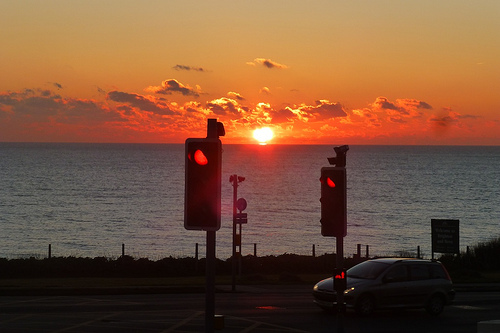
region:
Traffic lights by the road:
[172, 114, 369, 261]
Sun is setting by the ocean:
[215, 83, 355, 183]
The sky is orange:
[132, 10, 347, 140]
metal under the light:
[182, 223, 240, 327]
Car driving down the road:
[314, 235, 478, 312]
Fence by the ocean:
[20, 210, 258, 266]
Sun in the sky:
[233, 114, 296, 161]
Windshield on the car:
[335, 249, 385, 286]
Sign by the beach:
[423, 206, 463, 256]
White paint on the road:
[125, 289, 192, 323]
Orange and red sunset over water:
[1, 3, 494, 250]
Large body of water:
[1, 142, 498, 258]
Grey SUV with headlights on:
[311, 253, 458, 318]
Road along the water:
[0, 235, 499, 328]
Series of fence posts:
[0, 241, 477, 261]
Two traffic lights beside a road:
[183, 117, 350, 329]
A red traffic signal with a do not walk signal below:
[318, 116, 349, 331]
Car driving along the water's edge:
[309, 226, 457, 330]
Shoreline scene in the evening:
[2, 1, 498, 330]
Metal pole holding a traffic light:
[181, 113, 222, 330]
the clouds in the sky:
[0, 52, 499, 147]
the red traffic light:
[192, 148, 208, 163]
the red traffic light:
[324, 175, 336, 187]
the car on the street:
[313, 256, 453, 314]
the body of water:
[3, 141, 498, 256]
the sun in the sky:
[250, 125, 274, 143]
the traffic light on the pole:
[182, 115, 220, 331]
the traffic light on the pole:
[320, 143, 348, 331]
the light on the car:
[343, 286, 354, 295]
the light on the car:
[312, 282, 318, 289]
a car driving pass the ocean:
[318, 250, 490, 308]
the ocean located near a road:
[56, 120, 442, 254]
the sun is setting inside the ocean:
[233, 86, 315, 184]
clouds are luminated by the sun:
[166, 79, 358, 141]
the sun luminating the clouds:
[238, 95, 295, 171]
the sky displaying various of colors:
[26, 95, 442, 158]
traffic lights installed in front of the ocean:
[150, 128, 365, 218]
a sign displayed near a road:
[407, 207, 475, 259]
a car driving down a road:
[292, 253, 479, 306]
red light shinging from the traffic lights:
[163, 142, 360, 214]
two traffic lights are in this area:
[172, 113, 364, 244]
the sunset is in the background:
[16, 44, 496, 161]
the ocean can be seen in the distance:
[23, 150, 498, 270]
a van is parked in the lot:
[308, 245, 452, 313]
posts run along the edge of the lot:
[11, 239, 421, 271]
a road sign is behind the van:
[417, 209, 466, 261]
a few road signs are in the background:
[232, 188, 249, 235]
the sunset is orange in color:
[125, 89, 378, 164]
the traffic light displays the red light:
[181, 138, 226, 171]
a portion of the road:
[9, 281, 417, 331]